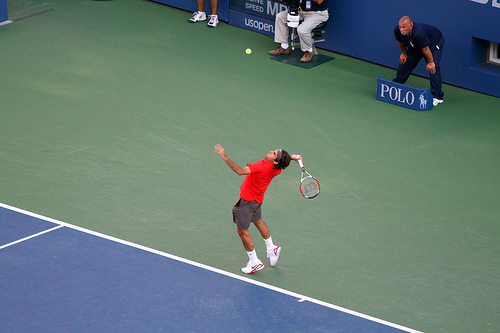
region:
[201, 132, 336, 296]
male tennis player posed about to hit the ball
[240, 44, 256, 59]
the green tennis ball in the air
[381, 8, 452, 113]
a bald man bent over watching the tennis match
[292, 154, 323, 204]
the red and white tennis racket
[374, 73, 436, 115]
a small blue sign advertising Polo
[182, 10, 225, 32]
white tennis shows someone is wearing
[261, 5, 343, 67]
a man with khaki pants sitting on the sidelines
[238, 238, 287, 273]
white tennis shoes and white socks the player is wearing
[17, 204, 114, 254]
white lines drawn on the tennis court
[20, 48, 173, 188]
green surface of the tennis court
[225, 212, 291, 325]
a man in red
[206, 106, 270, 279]
a man in red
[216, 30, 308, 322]
a man in red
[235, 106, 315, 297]
a man in red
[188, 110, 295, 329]
a man in red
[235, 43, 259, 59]
a tennis ball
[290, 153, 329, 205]
a man is holdind a tennis racket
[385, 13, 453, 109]
a person is watching if the ball goes out of bounce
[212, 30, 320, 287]
a tennis player is about to serve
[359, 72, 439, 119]
a small polo Ralph Lauren sign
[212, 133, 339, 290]
a tennis player is wearing a red T-shirt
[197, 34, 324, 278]
a tennis player is throwing a tennis ball in the air.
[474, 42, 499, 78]
a small window overlooking the tennis court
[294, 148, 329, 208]
A Wilson tennis racket.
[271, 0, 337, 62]
a tennis court judge is sitting down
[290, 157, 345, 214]
red white and blue tennisd racket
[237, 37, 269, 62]
yellow tennis ball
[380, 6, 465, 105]
tennis official dressed in all blue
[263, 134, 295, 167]
man wearing gray head band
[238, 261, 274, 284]
white tennis shoes with red and black detail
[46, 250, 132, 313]
blue tennis court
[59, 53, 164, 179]
green tennis court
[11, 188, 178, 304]
white lines painted on tennis court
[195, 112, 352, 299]
tennis player hitting tennis ball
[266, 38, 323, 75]
mens brown dress loafers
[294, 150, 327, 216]
red and white tennis racket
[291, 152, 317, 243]
red and white tennis racket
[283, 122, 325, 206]
red and white tennis racket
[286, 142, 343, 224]
red and white tennis racket